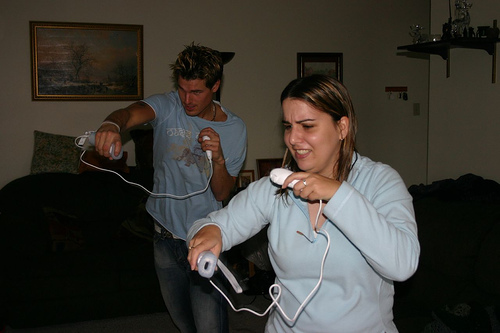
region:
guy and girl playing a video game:
[71, 36, 431, 331]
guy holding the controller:
[63, 122, 235, 195]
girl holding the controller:
[187, 152, 362, 325]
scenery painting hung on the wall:
[25, 13, 153, 108]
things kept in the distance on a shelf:
[386, 2, 498, 90]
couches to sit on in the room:
[1, 156, 498, 331]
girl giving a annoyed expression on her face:
[265, 73, 362, 180]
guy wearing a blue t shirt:
[88, 40, 251, 266]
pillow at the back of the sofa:
[26, 123, 131, 183]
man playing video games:
[145, 50, 245, 242]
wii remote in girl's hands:
[270, 162, 319, 207]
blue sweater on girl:
[234, 160, 399, 328]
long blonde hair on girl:
[281, 77, 369, 199]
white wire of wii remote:
[212, 201, 342, 313]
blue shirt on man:
[137, 94, 259, 241]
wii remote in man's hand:
[80, 124, 145, 165]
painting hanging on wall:
[32, 19, 146, 102]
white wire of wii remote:
[67, 157, 224, 202]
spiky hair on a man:
[161, 43, 236, 127]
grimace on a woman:
[278, 104, 336, 170]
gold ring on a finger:
[182, 237, 198, 257]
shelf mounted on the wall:
[386, 13, 498, 88]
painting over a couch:
[17, 7, 156, 109]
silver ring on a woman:
[298, 174, 310, 190]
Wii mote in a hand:
[82, 124, 125, 168]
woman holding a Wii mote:
[259, 164, 319, 206]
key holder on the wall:
[379, 76, 416, 106]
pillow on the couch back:
[27, 113, 88, 182]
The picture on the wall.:
[16, 19, 151, 106]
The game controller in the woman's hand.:
[194, 246, 222, 276]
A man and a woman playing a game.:
[52, 45, 419, 320]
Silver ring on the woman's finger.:
[301, 179, 305, 188]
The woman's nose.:
[288, 130, 298, 145]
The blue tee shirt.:
[136, 93, 240, 250]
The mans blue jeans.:
[148, 219, 230, 331]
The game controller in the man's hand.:
[197, 125, 219, 167]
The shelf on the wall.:
[398, 8, 497, 79]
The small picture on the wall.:
[291, 41, 366, 83]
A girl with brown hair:
[280, 78, 362, 168]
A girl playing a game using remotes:
[197, 77, 425, 297]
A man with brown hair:
[164, 40, 231, 115]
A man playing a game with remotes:
[77, 39, 255, 186]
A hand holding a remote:
[177, 220, 225, 277]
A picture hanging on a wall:
[28, 19, 152, 104]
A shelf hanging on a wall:
[392, 16, 498, 83]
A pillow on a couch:
[25, 125, 74, 192]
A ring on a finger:
[282, 174, 339, 196]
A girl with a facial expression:
[277, 110, 342, 167]